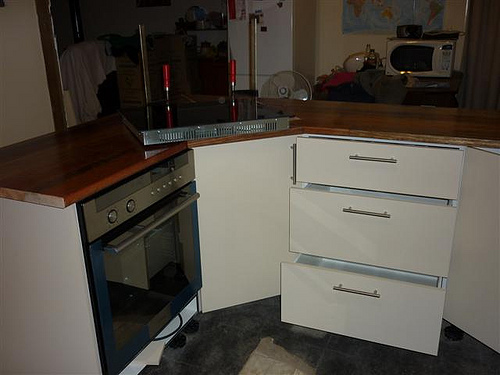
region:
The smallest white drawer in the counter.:
[292, 135, 465, 200]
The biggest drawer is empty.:
[280, 260, 446, 357]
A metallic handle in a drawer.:
[330, 281, 380, 297]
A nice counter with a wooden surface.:
[0, 95, 496, 372]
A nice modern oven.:
[76, 145, 202, 372]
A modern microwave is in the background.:
[382, 37, 457, 79]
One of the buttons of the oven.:
[125, 196, 137, 213]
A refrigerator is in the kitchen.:
[225, 1, 317, 96]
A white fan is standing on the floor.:
[260, 67, 313, 99]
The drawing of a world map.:
[340, 0, 445, 37]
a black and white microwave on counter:
[374, 23, 465, 83]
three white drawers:
[290, 122, 458, 366]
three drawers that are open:
[270, 138, 470, 363]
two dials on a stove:
[93, 193, 140, 236]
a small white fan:
[255, 63, 318, 109]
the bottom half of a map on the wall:
[325, 0, 450, 35]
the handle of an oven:
[105, 188, 201, 261]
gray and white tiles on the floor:
[150, 319, 415, 373]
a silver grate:
[117, 109, 298, 156]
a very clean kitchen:
[5, 8, 487, 373]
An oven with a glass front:
[0, 146, 205, 373]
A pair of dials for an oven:
[104, 199, 137, 226]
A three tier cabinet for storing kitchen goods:
[278, 130, 463, 356]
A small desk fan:
[256, 68, 311, 100]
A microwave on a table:
[384, 40, 455, 78]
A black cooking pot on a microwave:
[394, 21, 423, 38]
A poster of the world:
[339, 0, 444, 34]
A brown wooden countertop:
[0, 103, 497, 208]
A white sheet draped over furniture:
[51, 34, 123, 127]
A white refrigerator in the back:
[229, 0, 310, 102]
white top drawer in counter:
[291, 130, 466, 202]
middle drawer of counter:
[280, 186, 460, 276]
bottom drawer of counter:
[269, 254, 451, 356]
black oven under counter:
[74, 148, 209, 374]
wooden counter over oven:
[4, 105, 139, 216]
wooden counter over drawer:
[287, 96, 491, 148]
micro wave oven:
[382, 40, 459, 80]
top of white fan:
[261, 71, 313, 100]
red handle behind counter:
[158, 60, 183, 110]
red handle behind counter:
[226, 62, 241, 94]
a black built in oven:
[76, 150, 206, 372]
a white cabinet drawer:
[282, 257, 447, 358]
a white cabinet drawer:
[286, 185, 458, 285]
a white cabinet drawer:
[294, 135, 465, 207]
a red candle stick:
[160, 62, 173, 90]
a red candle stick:
[230, 57, 237, 82]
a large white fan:
[262, 70, 312, 105]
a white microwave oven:
[384, 36, 454, 79]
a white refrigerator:
[229, 0, 298, 87]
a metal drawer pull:
[344, 152, 399, 166]